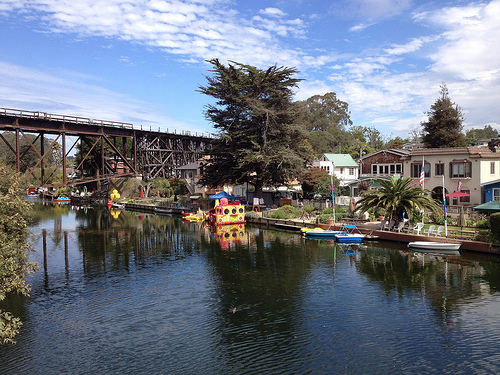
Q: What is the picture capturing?
A: A lake.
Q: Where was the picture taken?
A: Across from a lake.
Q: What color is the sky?
A: Blue.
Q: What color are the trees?
A: Green.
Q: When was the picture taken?
A: During the day.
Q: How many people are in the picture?
A: None.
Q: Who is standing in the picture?
A: No one.